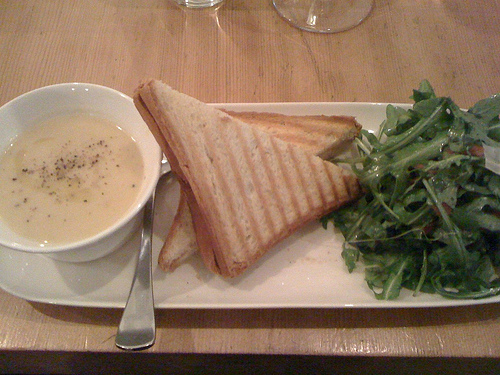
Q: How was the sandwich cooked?
A: Toasted.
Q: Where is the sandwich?
A: On the plate.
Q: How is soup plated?
A: In a bowl.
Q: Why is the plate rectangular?
A: To look nice.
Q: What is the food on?
A: The table.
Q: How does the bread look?
A: Toasted.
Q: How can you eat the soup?
A: With the spoon.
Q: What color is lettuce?
A: Green.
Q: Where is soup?
A: In a bowl.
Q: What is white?
A: A plate.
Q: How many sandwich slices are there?
A: Two.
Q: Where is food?
A: On a plate.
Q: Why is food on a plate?
A: To be eaten.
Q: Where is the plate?
A: On a table.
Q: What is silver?
A: A spoon.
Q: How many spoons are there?
A: One.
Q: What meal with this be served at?
A: Lunch.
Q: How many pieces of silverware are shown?
A: 1.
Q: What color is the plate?
A: White.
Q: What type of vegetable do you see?
A: Arugula.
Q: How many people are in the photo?
A: None.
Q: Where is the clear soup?
A: There is none.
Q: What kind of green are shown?
A: Arugula.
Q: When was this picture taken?
A: Lunchtime.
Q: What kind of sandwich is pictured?
A: A grilled cheese.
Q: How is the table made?
A: Of wood.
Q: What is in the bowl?
A: Soup.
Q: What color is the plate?
A: White.